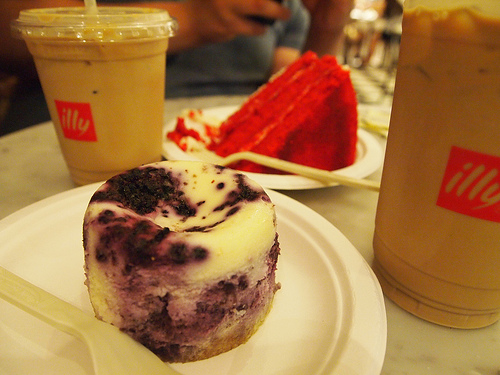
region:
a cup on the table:
[18, 20, 172, 166]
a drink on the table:
[30, 21, 169, 172]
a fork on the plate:
[12, 263, 137, 366]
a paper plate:
[7, 190, 382, 370]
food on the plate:
[95, 152, 250, 309]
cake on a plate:
[202, 60, 342, 151]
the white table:
[0, 122, 65, 192]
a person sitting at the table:
[173, 20, 283, 72]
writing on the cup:
[50, 92, 107, 138]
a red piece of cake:
[223, 68, 333, 156]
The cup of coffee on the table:
[6, 0, 184, 191]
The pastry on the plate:
[74, 152, 296, 360]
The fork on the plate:
[4, 270, 182, 372]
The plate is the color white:
[7, 170, 397, 366]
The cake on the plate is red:
[212, 50, 364, 170]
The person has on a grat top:
[166, 1, 316, 101]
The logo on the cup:
[48, 95, 100, 147]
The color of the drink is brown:
[65, 55, 170, 162]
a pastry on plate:
[78, 156, 287, 366]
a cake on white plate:
[79, 162, 295, 365]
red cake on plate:
[222, 57, 363, 178]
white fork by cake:
[186, 132, 388, 203]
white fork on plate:
[186, 139, 391, 206]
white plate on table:
[152, 74, 385, 190]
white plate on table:
[3, 173, 433, 373]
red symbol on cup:
[51, 90, 105, 147]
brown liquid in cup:
[23, 10, 184, 183]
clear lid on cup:
[18, 9, 180, 41]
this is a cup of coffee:
[22, 3, 187, 209]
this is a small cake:
[63, 148, 293, 363]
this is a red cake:
[194, 39, 386, 179]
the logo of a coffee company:
[45, 90, 106, 150]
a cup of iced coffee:
[359, 8, 498, 345]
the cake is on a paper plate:
[0, 135, 407, 370]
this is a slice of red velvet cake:
[172, 50, 396, 198]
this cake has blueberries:
[79, 152, 280, 372]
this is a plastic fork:
[169, 133, 394, 208]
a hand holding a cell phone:
[200, 0, 302, 50]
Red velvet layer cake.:
[200, 55, 365, 165]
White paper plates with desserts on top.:
[0, 53, 381, 373]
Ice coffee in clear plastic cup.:
[6, 3, 179, 196]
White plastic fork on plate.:
[166, 123, 394, 201]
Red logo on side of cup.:
[51, 99, 100, 146]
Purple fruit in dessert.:
[89, 158, 186, 272]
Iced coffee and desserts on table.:
[2, 5, 491, 364]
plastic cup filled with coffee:
[12, 0, 177, 185]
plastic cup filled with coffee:
[371, 0, 498, 329]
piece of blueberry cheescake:
[84, 160, 279, 361]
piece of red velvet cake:
[207, 55, 359, 162]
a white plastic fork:
[184, 150, 380, 192]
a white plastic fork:
[1, 268, 181, 375]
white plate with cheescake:
[1, 162, 386, 374]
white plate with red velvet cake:
[163, 52, 383, 190]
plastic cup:
[10, 1, 174, 185]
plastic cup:
[369, 0, 499, 327]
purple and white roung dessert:
[84, 158, 279, 362]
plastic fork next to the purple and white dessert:
[0, 265, 182, 373]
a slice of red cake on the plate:
[206, 50, 356, 171]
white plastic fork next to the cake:
[186, 139, 379, 191]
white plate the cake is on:
[161, 105, 382, 188]